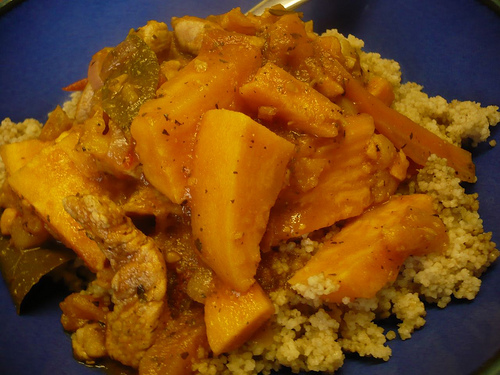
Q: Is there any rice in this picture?
A: Yes, there is rice.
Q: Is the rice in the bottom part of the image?
A: Yes, the rice is in the bottom of the image.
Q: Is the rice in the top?
A: No, the rice is in the bottom of the image.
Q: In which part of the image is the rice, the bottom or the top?
A: The rice is in the bottom of the image.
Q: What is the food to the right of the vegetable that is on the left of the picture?
A: The food is rice.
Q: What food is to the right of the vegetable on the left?
A: The food is rice.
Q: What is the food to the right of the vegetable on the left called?
A: The food is rice.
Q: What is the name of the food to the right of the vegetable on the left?
A: The food is rice.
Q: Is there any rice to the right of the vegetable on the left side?
A: Yes, there is rice to the right of the vegetable.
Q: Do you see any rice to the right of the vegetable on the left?
A: Yes, there is rice to the right of the vegetable.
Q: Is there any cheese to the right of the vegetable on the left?
A: No, there is rice to the right of the vegetable.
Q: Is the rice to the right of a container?
A: No, the rice is to the right of a vegetable.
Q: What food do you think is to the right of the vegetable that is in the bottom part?
A: The food is rice.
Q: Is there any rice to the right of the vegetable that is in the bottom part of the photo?
A: Yes, there is rice to the right of the vegetable.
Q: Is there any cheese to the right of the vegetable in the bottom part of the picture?
A: No, there is rice to the right of the vegetable.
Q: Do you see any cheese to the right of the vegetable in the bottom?
A: No, there is rice to the right of the vegetable.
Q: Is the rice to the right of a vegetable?
A: Yes, the rice is to the right of a vegetable.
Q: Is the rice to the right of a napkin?
A: No, the rice is to the right of a vegetable.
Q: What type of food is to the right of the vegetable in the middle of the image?
A: The food is rice.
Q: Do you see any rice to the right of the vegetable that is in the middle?
A: Yes, there is rice to the right of the vegetable.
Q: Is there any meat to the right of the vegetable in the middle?
A: No, there is rice to the right of the vegetable.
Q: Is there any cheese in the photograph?
A: No, there is no cheese.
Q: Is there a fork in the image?
A: No, there are no forks.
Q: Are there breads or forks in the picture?
A: No, there are no forks or breads.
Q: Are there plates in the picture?
A: Yes, there is a plate.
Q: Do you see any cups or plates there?
A: Yes, there is a plate.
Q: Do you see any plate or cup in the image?
A: Yes, there is a plate.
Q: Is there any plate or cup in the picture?
A: Yes, there is a plate.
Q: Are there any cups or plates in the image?
A: Yes, there is a plate.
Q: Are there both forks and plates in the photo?
A: No, there is a plate but no forks.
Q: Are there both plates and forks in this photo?
A: No, there is a plate but no forks.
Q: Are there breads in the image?
A: No, there are no breads.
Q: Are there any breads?
A: No, there are no breads.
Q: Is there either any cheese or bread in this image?
A: No, there are no breads or cheese.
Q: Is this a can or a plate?
A: This is a plate.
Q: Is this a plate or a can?
A: This is a plate.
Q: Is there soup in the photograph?
A: No, there is no soup.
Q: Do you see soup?
A: No, there is no soup.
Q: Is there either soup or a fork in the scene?
A: No, there are no soup or forks.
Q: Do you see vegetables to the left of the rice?
A: Yes, there is a vegetable to the left of the rice.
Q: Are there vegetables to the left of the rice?
A: Yes, there is a vegetable to the left of the rice.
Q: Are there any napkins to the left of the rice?
A: No, there is a vegetable to the left of the rice.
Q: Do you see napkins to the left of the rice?
A: No, there is a vegetable to the left of the rice.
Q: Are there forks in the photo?
A: No, there are no forks.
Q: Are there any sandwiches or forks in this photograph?
A: No, there are no forks or sandwiches.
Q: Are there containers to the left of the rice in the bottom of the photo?
A: No, there is a vegetable to the left of the rice.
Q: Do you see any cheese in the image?
A: No, there is no cheese.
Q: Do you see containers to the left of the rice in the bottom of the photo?
A: No, there is a vegetable to the left of the rice.